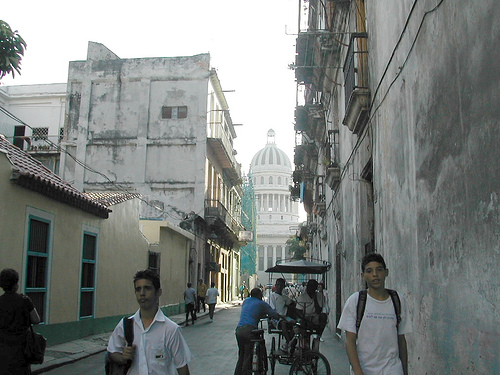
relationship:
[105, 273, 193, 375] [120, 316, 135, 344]
boy carrying backpack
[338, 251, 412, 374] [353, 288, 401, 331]
boy carrying backpack